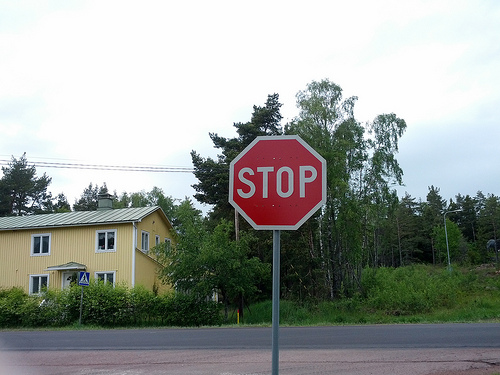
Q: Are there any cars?
A: No, there are no cars.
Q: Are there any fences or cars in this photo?
A: No, there are no cars or fences.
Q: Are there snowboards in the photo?
A: No, there are no snowboards.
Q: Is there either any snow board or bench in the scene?
A: No, there are no snowboards or benches.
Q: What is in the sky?
A: The clouds are in the sky.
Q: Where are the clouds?
A: The clouds are in the sky.